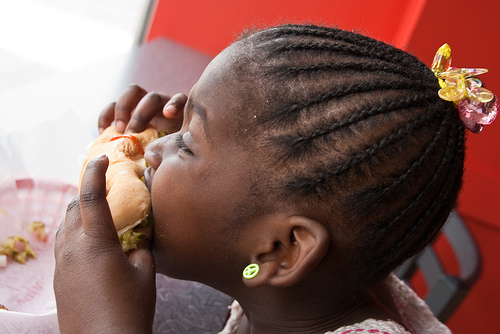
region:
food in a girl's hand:
[81, 120, 158, 255]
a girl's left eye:
[175, 130, 205, 165]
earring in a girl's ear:
[241, 261, 260, 280]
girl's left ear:
[239, 211, 328, 290]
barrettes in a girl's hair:
[431, 40, 498, 139]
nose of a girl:
[140, 138, 164, 167]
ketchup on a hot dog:
[108, 133, 140, 149]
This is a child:
[24, 14, 495, 332]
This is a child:
[32, 12, 498, 324]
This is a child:
[47, 17, 497, 327]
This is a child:
[39, 19, 493, 331]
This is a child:
[39, 14, 497, 329]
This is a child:
[39, 19, 498, 317]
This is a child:
[41, 20, 440, 330]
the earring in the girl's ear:
[242, 263, 260, 278]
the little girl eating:
[53, 22, 496, 332]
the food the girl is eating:
[78, 115, 157, 255]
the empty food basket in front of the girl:
[1, 175, 78, 332]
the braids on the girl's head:
[252, 23, 461, 280]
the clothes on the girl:
[214, 272, 450, 332]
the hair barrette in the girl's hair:
[432, 42, 499, 134]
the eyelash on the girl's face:
[174, 132, 192, 154]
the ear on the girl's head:
[240, 213, 330, 289]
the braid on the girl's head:
[253, 58, 440, 82]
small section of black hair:
[239, 190, 266, 222]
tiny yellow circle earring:
[233, 260, 266, 283]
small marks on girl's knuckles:
[63, 185, 110, 202]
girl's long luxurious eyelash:
[161, 123, 211, 158]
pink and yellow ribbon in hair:
[422, 33, 493, 149]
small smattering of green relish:
[120, 221, 142, 251]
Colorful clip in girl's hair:
[434, 35, 499, 132]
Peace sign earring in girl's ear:
[243, 263, 257, 274]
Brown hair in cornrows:
[255, 23, 462, 260]